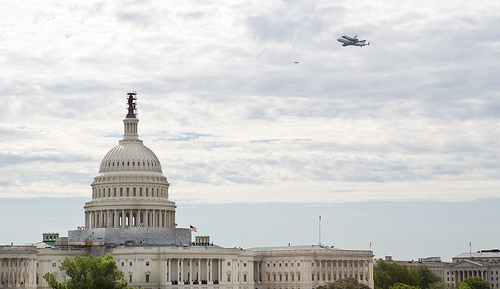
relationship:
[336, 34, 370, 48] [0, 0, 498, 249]
airplane in sky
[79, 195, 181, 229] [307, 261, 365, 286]
row of pillars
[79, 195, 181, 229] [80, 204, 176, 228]
row of pillars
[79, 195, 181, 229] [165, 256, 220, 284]
row of pillars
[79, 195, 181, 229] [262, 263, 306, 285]
row of pillars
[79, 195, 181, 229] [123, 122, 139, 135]
row of pillars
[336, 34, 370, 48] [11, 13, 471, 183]
airplane flying in air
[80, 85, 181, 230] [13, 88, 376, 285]
dome above building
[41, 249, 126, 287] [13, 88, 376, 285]
tree in front of building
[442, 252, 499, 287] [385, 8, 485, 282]
building to right right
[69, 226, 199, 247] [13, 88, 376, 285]
partition on building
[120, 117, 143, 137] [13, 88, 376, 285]
tower on top of building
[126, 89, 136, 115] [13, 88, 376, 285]
antennas on top of building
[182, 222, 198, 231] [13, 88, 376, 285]
american flag on building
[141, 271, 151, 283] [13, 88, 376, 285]
window on building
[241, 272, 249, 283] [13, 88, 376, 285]
window on building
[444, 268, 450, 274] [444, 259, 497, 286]
window on building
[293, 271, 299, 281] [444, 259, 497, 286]
window on building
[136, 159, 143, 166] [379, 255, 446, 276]
window on building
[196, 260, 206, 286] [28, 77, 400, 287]
column on building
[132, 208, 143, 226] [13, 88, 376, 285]
column on building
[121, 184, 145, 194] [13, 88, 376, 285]
column on building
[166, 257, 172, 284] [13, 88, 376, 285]
column on building